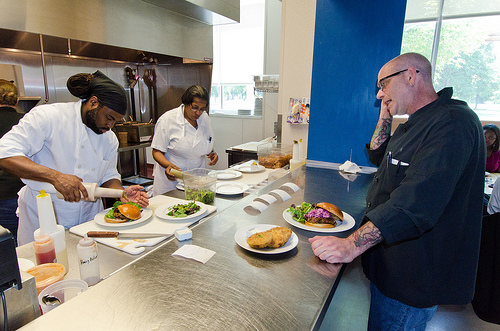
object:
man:
[308, 52, 487, 331]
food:
[288, 202, 343, 229]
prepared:
[107, 188, 151, 211]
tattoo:
[369, 118, 390, 152]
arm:
[353, 141, 471, 251]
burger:
[304, 202, 343, 228]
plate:
[283, 205, 356, 233]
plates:
[208, 169, 242, 180]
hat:
[81, 69, 128, 115]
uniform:
[149, 106, 215, 198]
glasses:
[377, 69, 420, 90]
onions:
[303, 208, 333, 220]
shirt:
[364, 87, 488, 279]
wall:
[316, 16, 361, 119]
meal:
[105, 199, 143, 224]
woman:
[151, 77, 219, 197]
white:
[168, 126, 183, 155]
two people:
[0, 70, 216, 247]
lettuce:
[165, 201, 200, 218]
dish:
[154, 200, 206, 220]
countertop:
[229, 209, 251, 224]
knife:
[87, 230, 170, 239]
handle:
[86, 230, 119, 237]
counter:
[321, 169, 369, 203]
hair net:
[186, 85, 206, 96]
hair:
[181, 84, 209, 106]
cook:
[0, 78, 26, 139]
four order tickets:
[243, 182, 300, 213]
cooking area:
[110, 177, 347, 285]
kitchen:
[12, 12, 495, 330]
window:
[390, 0, 500, 126]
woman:
[480, 125, 500, 172]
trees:
[434, 46, 497, 107]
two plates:
[234, 202, 355, 256]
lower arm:
[349, 221, 381, 253]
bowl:
[181, 168, 218, 204]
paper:
[172, 244, 217, 264]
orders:
[244, 200, 269, 213]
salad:
[286, 200, 315, 223]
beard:
[85, 109, 109, 135]